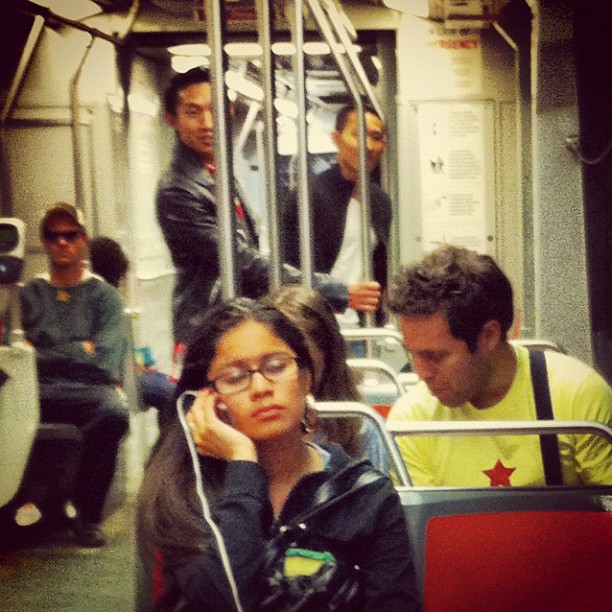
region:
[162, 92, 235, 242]
this man is asian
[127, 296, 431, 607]
the girl is on the phone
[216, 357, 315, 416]
the girl has glasses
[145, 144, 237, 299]
the man has a leather jacket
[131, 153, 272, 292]
the jacket is black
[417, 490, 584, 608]
the seats are red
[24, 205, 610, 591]
people are sitting in a subway car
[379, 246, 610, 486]
the man has a yellow shirt on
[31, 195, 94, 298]
the man is wearing a cap and sunglasses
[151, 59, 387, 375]
two men are standing on the train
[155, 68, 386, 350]
a man is holding on to the rails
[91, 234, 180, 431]
a man is sitting facing the aisle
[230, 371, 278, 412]
the nose of a woman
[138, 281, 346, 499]
the hair of a woman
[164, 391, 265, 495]
the hand of a woman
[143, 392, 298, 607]
the arm of a woman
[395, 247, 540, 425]
the head of a man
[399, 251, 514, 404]
person has a head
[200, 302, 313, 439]
person has a head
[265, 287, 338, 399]
person has a head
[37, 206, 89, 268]
person has a head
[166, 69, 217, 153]
person has a head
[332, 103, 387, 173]
person has a head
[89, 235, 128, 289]
person has a head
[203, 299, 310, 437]
eyeglasses on woman's face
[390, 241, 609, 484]
man in yellow shirt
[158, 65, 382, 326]
man holding metal bar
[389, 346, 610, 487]
yellow shirt with red star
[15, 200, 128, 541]
seated man with folded arms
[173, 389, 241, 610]
white wire hanging from fingers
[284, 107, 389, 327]
man in white shirt and jacket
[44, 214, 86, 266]
sunglasses on man's face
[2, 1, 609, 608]
interior of subway train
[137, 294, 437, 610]
woman listening to music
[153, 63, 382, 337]
man wearing leather jacket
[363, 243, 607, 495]
man wearing yellow shirt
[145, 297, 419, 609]
woman wearing glasses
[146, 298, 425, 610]
woman wearing long-sleeved coat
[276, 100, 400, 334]
man wearing long-sleeved coat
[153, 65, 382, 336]
man holding onto pole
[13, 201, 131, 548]
Man sitting down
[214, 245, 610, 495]
Two people sitting next to each other on subway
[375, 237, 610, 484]
Man carrying a bag